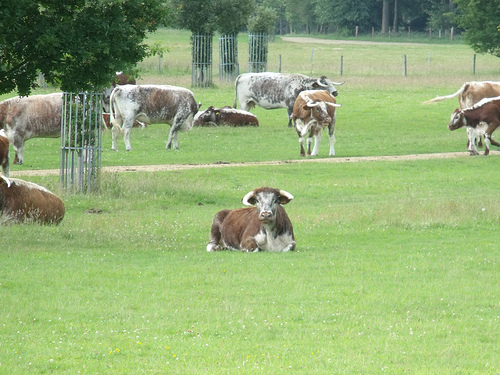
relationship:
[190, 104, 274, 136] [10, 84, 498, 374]
animal laying in grass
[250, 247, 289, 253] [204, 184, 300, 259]
hoofs under cow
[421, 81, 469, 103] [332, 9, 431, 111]
tail in air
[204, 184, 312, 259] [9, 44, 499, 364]
animal walking on grass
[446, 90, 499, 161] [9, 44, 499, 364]
animal walking on grass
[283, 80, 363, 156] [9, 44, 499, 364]
animal walking on grass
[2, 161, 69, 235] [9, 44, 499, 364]
animal walking on grass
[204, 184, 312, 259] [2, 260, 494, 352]
animal in pasture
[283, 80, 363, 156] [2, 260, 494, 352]
animal in pasture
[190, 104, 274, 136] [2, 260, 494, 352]
animal in pasture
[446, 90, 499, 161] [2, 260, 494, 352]
animal in pasture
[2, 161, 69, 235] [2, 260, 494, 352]
animal in pasture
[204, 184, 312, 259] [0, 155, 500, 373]
animal resting on ground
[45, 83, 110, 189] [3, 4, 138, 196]
enclosure has tree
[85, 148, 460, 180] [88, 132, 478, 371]
strip in field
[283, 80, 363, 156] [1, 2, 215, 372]
animal looking left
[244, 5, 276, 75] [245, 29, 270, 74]
trees have fence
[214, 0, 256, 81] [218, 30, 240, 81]
tree have fence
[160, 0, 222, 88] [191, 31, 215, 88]
trees have fence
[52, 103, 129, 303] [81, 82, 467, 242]
trunks of trees in back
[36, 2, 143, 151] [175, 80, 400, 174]
branches falling over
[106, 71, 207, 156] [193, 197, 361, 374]
animal looking down on ground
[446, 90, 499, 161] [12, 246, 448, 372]
animal walking different direction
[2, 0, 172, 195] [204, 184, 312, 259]
green tree near animal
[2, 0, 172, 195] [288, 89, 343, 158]
green tree near cow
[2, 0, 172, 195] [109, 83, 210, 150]
green tree near cow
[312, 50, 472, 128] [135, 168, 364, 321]
fence near cow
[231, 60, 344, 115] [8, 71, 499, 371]
animal on grass at back of field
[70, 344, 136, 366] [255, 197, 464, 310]
flower on grass